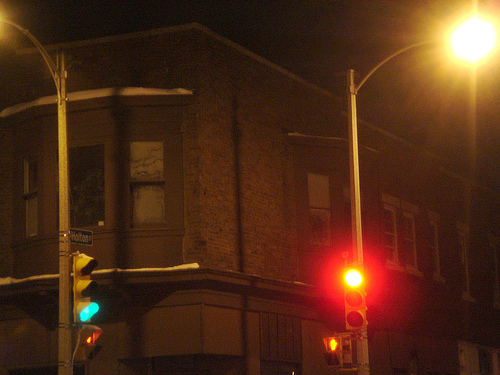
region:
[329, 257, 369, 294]
A glowing red light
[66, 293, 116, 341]
A green light on a pole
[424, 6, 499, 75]
a glowing street light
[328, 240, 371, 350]
a signal with a red light lit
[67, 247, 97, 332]
a signal with a green light lit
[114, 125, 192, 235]
a small window that has blocks on it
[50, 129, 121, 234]
a black window on a building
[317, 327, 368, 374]
a smaller signal with a red light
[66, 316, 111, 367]
a smaller signal with a red light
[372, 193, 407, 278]
a window on the side of the building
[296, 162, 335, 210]
This is a window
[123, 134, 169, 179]
This is a window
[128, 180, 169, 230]
This is a window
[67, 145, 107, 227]
This is a window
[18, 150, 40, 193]
This is a window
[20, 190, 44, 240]
This is a window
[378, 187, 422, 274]
This is a window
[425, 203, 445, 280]
This is a window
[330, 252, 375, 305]
This is a lamp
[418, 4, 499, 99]
This is a lamp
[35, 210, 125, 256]
green and white street sign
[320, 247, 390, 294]
red light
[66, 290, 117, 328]
green light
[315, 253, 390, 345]
traffic signal with blaring light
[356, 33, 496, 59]
yellow light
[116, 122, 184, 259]
window with two sections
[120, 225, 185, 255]
ledge of window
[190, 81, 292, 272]
brown bricks on side of building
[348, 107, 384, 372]
light pole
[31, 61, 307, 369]
brown brick building behind traffic light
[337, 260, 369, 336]
A red traffic light.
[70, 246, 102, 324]
A green traffic light.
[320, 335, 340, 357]
A road crossing light.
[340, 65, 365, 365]
A traffic light attached to a pole.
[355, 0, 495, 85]
A street light.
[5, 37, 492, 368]
A brick building near traffic lights.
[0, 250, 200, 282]
Snow on the ledge of the building.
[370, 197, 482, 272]
Windows with white frames.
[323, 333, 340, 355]
An orange light on the crossing sign.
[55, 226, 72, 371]
Metal rings around the pole.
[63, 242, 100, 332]
The traffic light is green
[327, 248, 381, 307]
The traffic signal is red.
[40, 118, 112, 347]
A traffic signal on pole.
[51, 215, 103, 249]
A green sign above the traffic signal.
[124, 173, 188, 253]
Window is boarded up.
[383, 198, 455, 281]
Windows on the building.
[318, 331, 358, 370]
A street walking light on pole.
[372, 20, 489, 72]
The street lights are on.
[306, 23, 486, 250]
Street light on the pole.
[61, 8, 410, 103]
It is nightime outside.